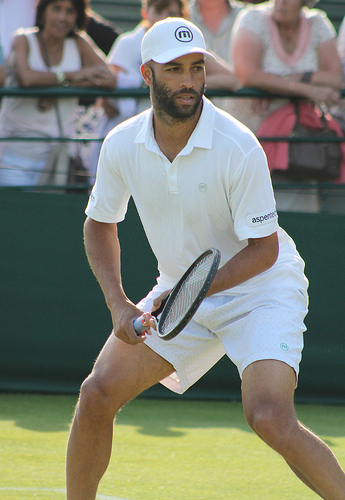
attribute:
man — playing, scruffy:
[119, 14, 290, 254]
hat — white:
[136, 11, 222, 66]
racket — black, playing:
[159, 256, 239, 337]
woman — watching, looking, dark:
[19, 6, 109, 86]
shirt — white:
[112, 125, 280, 254]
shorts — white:
[178, 367, 252, 412]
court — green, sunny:
[142, 426, 232, 465]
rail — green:
[25, 90, 65, 101]